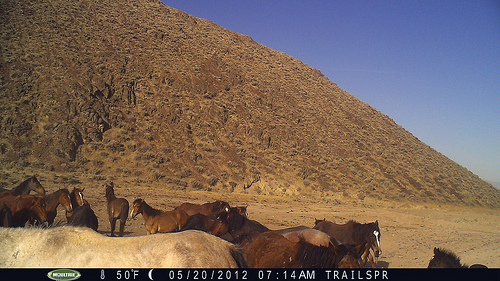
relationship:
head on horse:
[18, 162, 54, 209] [0, 163, 49, 216]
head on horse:
[69, 186, 89, 213] [56, 179, 110, 231]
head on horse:
[25, 174, 47, 198] [0, 171, 47, 199]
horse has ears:
[314, 213, 383, 259] [362, 216, 382, 226]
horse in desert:
[184, 214, 262, 235] [4, 7, 497, 271]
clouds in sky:
[354, 36, 498, 182] [182, 1, 498, 193]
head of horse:
[207, 196, 246, 234] [203, 196, 333, 274]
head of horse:
[99, 180, 119, 197] [97, 172, 133, 237]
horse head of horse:
[68, 183, 96, 217] [61, 187, 97, 231]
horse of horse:
[100, 180, 127, 234] [71, 181, 97, 222]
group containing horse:
[1, 169, 496, 278] [102, 183, 129, 234]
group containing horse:
[1, 169, 496, 278] [0, 192, 47, 227]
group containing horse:
[1, 169, 496, 278] [314, 215, 384, 265]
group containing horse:
[1, 169, 496, 278] [131, 196, 189, 233]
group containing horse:
[1, 169, 496, 278] [219, 205, 271, 242]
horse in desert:
[100, 180, 127, 234] [3, 186, 498, 265]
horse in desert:
[228, 229, 362, 271] [3, 186, 498, 265]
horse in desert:
[326, 213, 385, 256] [3, 186, 498, 265]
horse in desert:
[177, 198, 231, 215] [3, 186, 498, 265]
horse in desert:
[0, 192, 47, 222] [3, 186, 498, 265]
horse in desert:
[3, 185, 63, 229] [384, 202, 499, 245]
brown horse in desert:
[0, 172, 48, 194] [4, 7, 497, 271]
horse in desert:
[127, 198, 187, 232] [89, 62, 350, 279]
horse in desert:
[100, 180, 127, 234] [4, 7, 497, 271]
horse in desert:
[326, 213, 385, 256] [4, 7, 497, 271]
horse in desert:
[235, 229, 338, 272] [4, 7, 497, 271]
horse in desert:
[177, 198, 231, 215] [4, 7, 497, 271]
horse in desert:
[326, 213, 385, 256] [7, 171, 498, 272]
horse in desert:
[235, 228, 343, 273] [7, 171, 498, 272]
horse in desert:
[127, 198, 187, 232] [7, 171, 498, 272]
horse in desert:
[100, 180, 127, 234] [7, 171, 498, 272]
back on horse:
[0, 213, 235, 260] [7, 206, 259, 266]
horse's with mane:
[245, 216, 390, 268] [289, 244, 347, 268]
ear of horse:
[424, 240, 452, 258] [409, 211, 496, 279]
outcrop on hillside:
[43, 73, 155, 168] [3, 3, 496, 213]